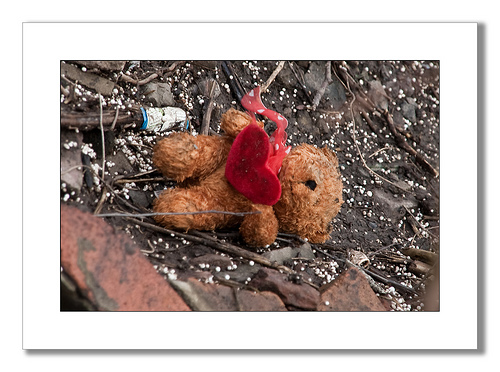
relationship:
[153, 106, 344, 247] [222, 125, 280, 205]
bear has a heart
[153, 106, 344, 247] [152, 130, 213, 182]
bear has a leg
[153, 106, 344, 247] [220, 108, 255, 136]
bear has an arm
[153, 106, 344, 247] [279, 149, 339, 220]
bear has a face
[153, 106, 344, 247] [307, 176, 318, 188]
bear has a nose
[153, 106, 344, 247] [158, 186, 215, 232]
bear has a right leg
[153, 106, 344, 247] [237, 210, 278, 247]
bear has a left arm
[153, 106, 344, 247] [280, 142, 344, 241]
bear has a head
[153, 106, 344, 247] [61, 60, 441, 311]
bear on ground